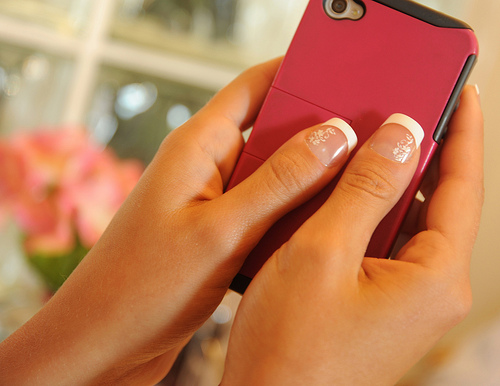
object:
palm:
[78, 130, 246, 369]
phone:
[224, 4, 480, 297]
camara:
[320, 0, 366, 22]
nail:
[304, 117, 358, 169]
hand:
[218, 83, 485, 385]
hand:
[1, 55, 356, 386]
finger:
[426, 80, 482, 242]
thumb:
[290, 112, 425, 278]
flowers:
[0, 124, 146, 256]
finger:
[303, 112, 422, 259]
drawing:
[308, 126, 336, 145]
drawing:
[393, 133, 414, 164]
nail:
[371, 108, 428, 167]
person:
[0, 54, 485, 386]